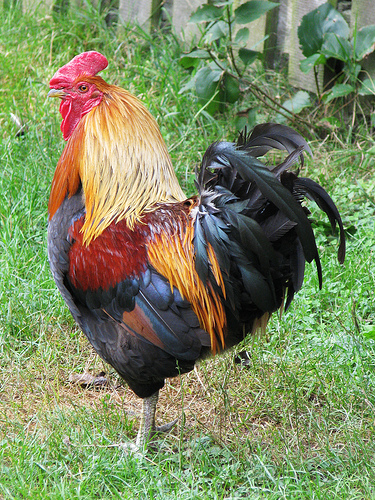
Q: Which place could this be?
A: It is a yard.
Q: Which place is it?
A: It is a yard.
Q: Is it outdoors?
A: Yes, it is outdoors.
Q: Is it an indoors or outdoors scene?
A: It is outdoors.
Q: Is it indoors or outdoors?
A: It is outdoors.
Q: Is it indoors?
A: No, it is outdoors.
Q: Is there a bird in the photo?
A: Yes, there is a bird.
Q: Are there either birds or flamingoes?
A: Yes, there is a bird.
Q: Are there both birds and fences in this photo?
A: Yes, there are both a bird and a fence.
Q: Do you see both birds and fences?
A: Yes, there are both a bird and a fence.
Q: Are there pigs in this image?
A: No, there are no pigs.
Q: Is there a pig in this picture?
A: No, there are no pigs.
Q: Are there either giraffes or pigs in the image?
A: No, there are no pigs or giraffes.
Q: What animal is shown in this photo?
A: The animal is a bird.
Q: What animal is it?
A: The animal is a bird.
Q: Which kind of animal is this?
A: This is a bird.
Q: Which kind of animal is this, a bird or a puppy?
A: This is a bird.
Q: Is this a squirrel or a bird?
A: This is a bird.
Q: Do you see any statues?
A: No, there are no statues.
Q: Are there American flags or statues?
A: No, there are no statues or American flags.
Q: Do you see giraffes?
A: No, there are no giraffes.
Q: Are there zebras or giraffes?
A: No, there are no giraffes or zebras.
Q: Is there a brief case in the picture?
A: No, there are no briefcases.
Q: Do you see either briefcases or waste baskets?
A: No, there are no briefcases or waste baskets.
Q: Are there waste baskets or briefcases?
A: No, there are no briefcases or waste baskets.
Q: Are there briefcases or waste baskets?
A: No, there are no briefcases or waste baskets.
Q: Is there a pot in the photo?
A: No, there are no pots.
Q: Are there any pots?
A: No, there are no pots.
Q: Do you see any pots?
A: No, there are no pots.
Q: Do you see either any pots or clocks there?
A: No, there are no pots or clocks.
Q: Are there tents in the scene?
A: No, there are no tents.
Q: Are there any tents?
A: No, there are no tents.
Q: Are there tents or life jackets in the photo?
A: No, there are no tents or life jackets.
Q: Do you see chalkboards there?
A: No, there are no chalkboards.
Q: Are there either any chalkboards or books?
A: No, there are no chalkboards or books.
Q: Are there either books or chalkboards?
A: No, there are no chalkboards or books.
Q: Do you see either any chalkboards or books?
A: No, there are no chalkboards or books.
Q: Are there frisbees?
A: No, there are no frisbees.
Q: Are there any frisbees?
A: No, there are no frisbees.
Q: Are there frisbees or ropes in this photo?
A: No, there are no frisbees or ropes.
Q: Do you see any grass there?
A: Yes, there is grass.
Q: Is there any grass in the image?
A: Yes, there is grass.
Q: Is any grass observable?
A: Yes, there is grass.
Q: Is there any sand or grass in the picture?
A: Yes, there is grass.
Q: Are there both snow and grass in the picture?
A: No, there is grass but no snow.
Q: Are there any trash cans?
A: No, there are no trash cans.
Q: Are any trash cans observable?
A: No, there are no trash cans.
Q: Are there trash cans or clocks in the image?
A: No, there are no trash cans or clocks.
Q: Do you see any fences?
A: Yes, there is a fence.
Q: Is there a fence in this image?
A: Yes, there is a fence.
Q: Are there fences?
A: Yes, there is a fence.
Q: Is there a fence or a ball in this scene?
A: Yes, there is a fence.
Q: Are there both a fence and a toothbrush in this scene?
A: No, there is a fence but no toothbrushes.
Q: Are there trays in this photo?
A: No, there are no trays.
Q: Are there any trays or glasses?
A: No, there are no trays or glasses.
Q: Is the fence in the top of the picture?
A: Yes, the fence is in the top of the image.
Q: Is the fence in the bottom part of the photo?
A: No, the fence is in the top of the image.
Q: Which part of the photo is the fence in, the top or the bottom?
A: The fence is in the top of the image.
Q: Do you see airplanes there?
A: No, there are no airplanes.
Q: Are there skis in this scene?
A: No, there are no skis.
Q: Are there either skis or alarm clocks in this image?
A: No, there are no skis or alarm clocks.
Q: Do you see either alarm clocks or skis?
A: No, there are no skis or alarm clocks.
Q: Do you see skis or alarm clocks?
A: No, there are no skis or alarm clocks.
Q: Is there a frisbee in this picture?
A: No, there are no frisbees.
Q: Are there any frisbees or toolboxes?
A: No, there are no frisbees or toolboxes.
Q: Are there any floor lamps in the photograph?
A: No, there are no floor lamps.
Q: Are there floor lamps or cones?
A: No, there are no floor lamps or cones.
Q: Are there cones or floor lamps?
A: No, there are no floor lamps or cones.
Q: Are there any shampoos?
A: No, there are no shampoos.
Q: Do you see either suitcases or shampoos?
A: No, there are no shampoos or suitcases.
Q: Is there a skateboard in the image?
A: No, there are no skateboards.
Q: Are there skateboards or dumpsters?
A: No, there are no skateboards or dumpsters.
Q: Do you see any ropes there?
A: No, there are no ropes.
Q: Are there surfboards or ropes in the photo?
A: No, there are no ropes or surfboards.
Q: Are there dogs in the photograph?
A: No, there are no dogs.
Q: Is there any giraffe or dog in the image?
A: No, there are no dogs or giraffes.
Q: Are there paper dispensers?
A: No, there are no paper dispensers.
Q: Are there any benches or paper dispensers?
A: No, there are no paper dispensers or benches.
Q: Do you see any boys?
A: No, there are no boys.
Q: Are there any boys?
A: No, there are no boys.